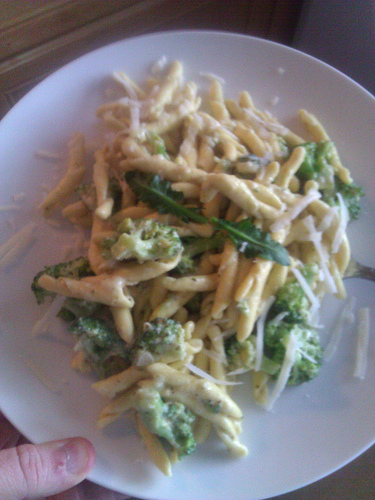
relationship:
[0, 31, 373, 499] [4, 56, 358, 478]
plate of food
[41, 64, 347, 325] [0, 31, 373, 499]
noodles on plate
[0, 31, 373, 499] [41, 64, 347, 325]
plate with noodles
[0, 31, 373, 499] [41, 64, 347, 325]
plate with cooked noodles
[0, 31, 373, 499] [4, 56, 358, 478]
plate with food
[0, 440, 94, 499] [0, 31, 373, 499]
thumb on plate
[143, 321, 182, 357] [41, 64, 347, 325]
broccoli mixed with noodles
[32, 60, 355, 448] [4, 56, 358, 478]
cheese over food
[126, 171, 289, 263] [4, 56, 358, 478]
leaves garnishing food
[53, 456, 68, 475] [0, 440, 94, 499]
broken skin on thumb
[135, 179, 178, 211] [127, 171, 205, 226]
stem through leaf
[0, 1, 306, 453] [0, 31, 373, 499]
wood behind plate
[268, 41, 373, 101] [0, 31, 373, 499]
edge of plate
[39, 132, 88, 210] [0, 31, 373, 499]
noodle on plate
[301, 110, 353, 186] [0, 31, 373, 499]
noodle on plate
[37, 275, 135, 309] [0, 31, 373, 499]
noodle on plate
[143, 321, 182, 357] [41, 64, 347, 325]
broccoli next to noodles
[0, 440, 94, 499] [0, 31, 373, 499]
thumb touching plate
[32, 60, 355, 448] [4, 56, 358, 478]
cheese on food